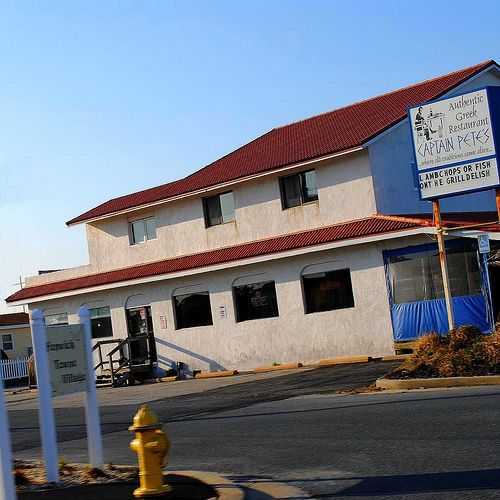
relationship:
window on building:
[299, 259, 357, 315] [5, 58, 500, 378]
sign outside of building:
[408, 84, 500, 202] [5, 58, 500, 378]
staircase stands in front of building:
[90, 332, 155, 387] [5, 58, 500, 378]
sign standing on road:
[408, 84, 500, 202] [224, 386, 500, 499]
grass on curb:
[395, 318, 500, 375] [375, 375, 500, 391]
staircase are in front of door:
[90, 332, 155, 387] [123, 305, 159, 365]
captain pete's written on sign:
[418, 128, 491, 156] [408, 84, 500, 202]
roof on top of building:
[64, 61, 493, 228] [5, 58, 500, 378]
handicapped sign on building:
[157, 315, 169, 329] [5, 58, 500, 378]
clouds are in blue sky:
[3, 193, 98, 314] [0, 0, 499, 317]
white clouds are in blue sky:
[3, 193, 98, 314] [0, 0, 190, 124]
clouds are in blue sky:
[3, 193, 67, 238] [0, 0, 499, 317]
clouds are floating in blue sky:
[3, 193, 98, 314] [0, 0, 190, 124]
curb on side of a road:
[375, 375, 500, 391] [2, 386, 499, 498]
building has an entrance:
[5, 58, 500, 378] [91, 303, 160, 388]